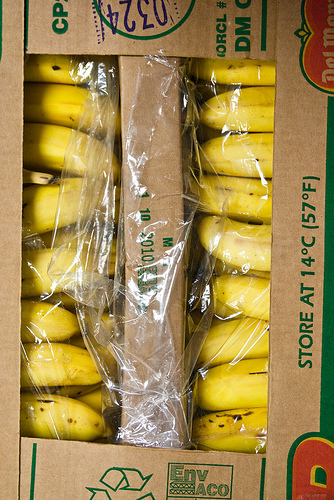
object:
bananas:
[19, 391, 107, 439]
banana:
[212, 274, 273, 321]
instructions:
[297, 174, 321, 371]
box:
[0, 0, 334, 498]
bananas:
[196, 211, 273, 272]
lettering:
[298, 360, 314, 371]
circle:
[94, 0, 195, 42]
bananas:
[24, 55, 98, 83]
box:
[118, 56, 189, 447]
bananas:
[196, 175, 274, 222]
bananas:
[22, 174, 102, 239]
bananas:
[197, 87, 275, 133]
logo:
[293, 0, 334, 97]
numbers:
[106, 3, 121, 36]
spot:
[229, 413, 243, 423]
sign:
[84, 465, 156, 500]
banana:
[191, 404, 267, 454]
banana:
[193, 357, 269, 411]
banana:
[19, 342, 103, 390]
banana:
[21, 298, 80, 344]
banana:
[196, 131, 276, 178]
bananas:
[23, 124, 123, 182]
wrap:
[20, 56, 278, 459]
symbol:
[72, 458, 122, 498]